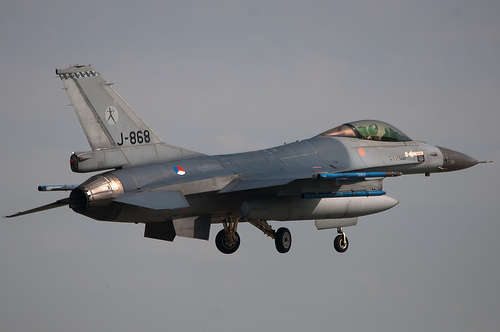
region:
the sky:
[311, 263, 356, 324]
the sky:
[377, 265, 402, 310]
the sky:
[333, 255, 370, 305]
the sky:
[363, 272, 408, 329]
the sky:
[336, 270, 351, 297]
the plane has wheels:
[214, 230, 376, 277]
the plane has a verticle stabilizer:
[52, 59, 175, 179]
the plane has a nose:
[432, 130, 494, 181]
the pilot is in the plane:
[357, 120, 387, 136]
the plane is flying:
[33, 61, 497, 260]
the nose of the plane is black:
[437, 135, 497, 181]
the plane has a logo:
[165, 156, 188, 179]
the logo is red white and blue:
[170, 162, 187, 180]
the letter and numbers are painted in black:
[104, 126, 152, 156]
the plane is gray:
[50, 59, 498, 268]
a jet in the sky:
[170, 95, 327, 267]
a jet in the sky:
[138, 114, 291, 314]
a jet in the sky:
[204, 124, 312, 323]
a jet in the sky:
[149, 62, 260, 277]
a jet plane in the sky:
[226, 146, 250, 186]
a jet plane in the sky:
[219, 187, 301, 272]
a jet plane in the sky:
[247, 163, 293, 239]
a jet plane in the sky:
[206, 199, 246, 286]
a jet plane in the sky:
[251, 162, 302, 302]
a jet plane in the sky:
[190, 107, 294, 262]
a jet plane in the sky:
[144, 173, 227, 232]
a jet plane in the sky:
[198, 110, 323, 295]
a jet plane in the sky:
[205, 116, 292, 321]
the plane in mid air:
[8, 63, 498, 253]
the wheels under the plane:
[213, 222, 348, 253]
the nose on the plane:
[444, 147, 479, 174]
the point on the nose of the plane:
[477, 157, 494, 164]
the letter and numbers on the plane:
[116, 130, 149, 145]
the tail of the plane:
[55, 56, 166, 170]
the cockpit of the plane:
[331, 120, 404, 143]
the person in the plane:
[367, 121, 378, 138]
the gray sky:
[143, 5, 408, 107]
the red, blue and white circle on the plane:
[173, 164, 184, 174]